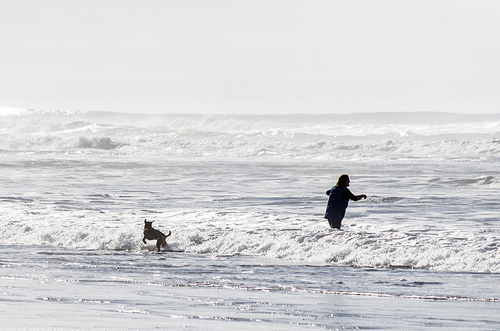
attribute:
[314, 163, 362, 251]
person — standing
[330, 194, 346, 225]
cloths — black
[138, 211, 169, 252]
dog — jumping, playing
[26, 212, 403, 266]
waves — rolling, glistening, large, moving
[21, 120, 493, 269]
water — choppy, shallow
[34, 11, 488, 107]
sky — white, gray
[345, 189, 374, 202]
arms — extended, raised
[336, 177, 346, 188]
hair — short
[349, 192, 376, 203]
arm — extended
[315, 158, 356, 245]
woman — forward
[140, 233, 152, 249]
feet — up